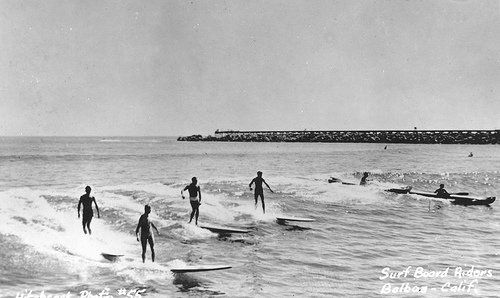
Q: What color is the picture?
A: Black and white.